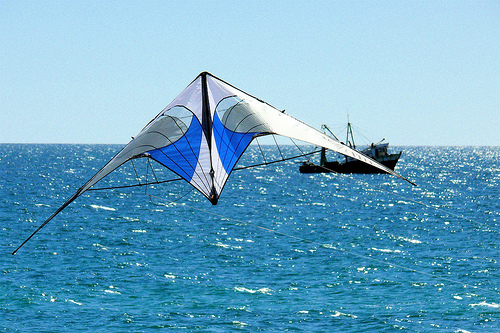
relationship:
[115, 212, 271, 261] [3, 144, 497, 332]
ripples in water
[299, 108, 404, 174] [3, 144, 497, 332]
boat in water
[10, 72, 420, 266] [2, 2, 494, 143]
kite in sky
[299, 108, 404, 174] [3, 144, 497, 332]
boat in ocean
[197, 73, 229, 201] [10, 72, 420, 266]
spine of kite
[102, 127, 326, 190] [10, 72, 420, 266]
spreader of kite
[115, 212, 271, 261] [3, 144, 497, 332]
ripples of water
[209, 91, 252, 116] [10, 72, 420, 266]
section of kite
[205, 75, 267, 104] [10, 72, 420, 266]
edge of kite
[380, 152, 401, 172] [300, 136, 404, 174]
front of boat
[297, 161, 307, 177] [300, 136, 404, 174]
back of boat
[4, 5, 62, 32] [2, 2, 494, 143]
section of sky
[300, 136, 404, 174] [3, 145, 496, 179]
boat in background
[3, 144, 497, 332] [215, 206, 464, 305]
ocean with waves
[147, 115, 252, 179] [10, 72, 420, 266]
triangles on kite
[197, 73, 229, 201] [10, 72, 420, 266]
stripe down kite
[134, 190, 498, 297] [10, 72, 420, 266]
strings attached to kite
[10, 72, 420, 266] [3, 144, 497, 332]
kite over ocean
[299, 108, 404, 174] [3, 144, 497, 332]
boat on water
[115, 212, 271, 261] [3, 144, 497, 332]
ripples across water